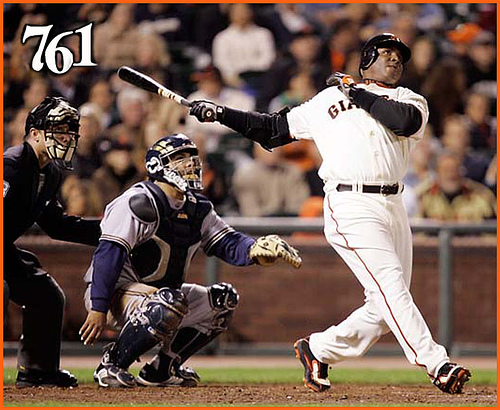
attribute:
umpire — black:
[3, 92, 102, 387]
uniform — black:
[0, 141, 102, 370]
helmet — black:
[351, 26, 414, 78]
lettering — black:
[334, 83, 389, 113]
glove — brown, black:
[247, 232, 303, 270]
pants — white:
[311, 185, 468, 397]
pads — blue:
[126, 201, 205, 296]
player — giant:
[116, 31, 479, 394]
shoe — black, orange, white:
[285, 336, 325, 391]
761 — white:
[18, 15, 100, 84]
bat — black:
[114, 63, 214, 120]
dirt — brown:
[132, 382, 393, 409]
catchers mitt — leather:
[246, 230, 305, 272]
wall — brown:
[234, 231, 497, 348]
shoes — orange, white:
[418, 347, 482, 402]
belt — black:
[328, 183, 401, 195]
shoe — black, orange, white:
[432, 359, 472, 399]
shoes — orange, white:
[292, 331, 335, 394]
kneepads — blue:
[146, 285, 191, 334]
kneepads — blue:
[207, 280, 239, 334]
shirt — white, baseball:
[284, 79, 428, 184]